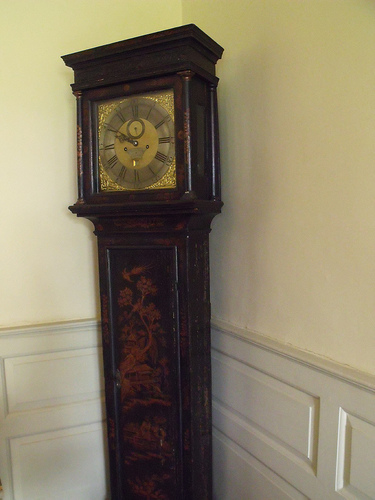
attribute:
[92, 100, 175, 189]
clock — shiny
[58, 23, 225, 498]
clock — big, wooden, tall, grandfather, stained, dark, bare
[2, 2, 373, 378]
wall — bare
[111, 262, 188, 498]
carving — decorative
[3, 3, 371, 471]
walls — white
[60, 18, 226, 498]
grandfather clock — antique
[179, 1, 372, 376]
wall — light yellow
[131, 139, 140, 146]
center — gold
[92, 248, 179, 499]
pattern — floral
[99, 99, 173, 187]
numerals — roman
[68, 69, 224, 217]
wood base — red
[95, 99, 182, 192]
clock — golden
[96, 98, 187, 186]
numerals — roman, black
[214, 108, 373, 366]
wall — wood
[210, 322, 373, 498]
wall — white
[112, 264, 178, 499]
design — gold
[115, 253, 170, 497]
image — floral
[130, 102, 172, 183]
numerals — roman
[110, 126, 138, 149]
hands — black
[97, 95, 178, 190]
face — golden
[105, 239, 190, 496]
decor — floral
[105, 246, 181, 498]
decorative portion — lighter, wood